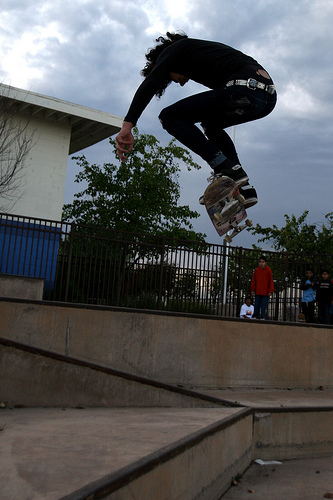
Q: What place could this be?
A: It is a park.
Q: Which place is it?
A: It is a park.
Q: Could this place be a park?
A: Yes, it is a park.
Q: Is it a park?
A: Yes, it is a park.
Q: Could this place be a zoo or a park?
A: It is a park.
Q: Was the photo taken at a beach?
A: No, the picture was taken in a park.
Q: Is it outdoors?
A: Yes, it is outdoors.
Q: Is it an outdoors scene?
A: Yes, it is outdoors.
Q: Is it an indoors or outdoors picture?
A: It is outdoors.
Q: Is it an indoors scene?
A: No, it is outdoors.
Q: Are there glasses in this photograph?
A: No, there are no glasses.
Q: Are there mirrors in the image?
A: No, there are no mirrors.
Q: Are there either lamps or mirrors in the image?
A: No, there are no mirrors or lamps.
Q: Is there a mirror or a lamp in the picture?
A: No, there are no mirrors or lamps.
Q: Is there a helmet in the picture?
A: No, there are no helmets.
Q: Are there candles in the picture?
A: No, there are no candles.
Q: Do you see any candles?
A: No, there are no candles.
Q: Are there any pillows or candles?
A: No, there are no candles or pillows.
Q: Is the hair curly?
A: Yes, the hair is curly.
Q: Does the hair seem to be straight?
A: No, the hair is curly.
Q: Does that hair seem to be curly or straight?
A: The hair is curly.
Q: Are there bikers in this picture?
A: No, there are no bikers.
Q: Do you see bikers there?
A: No, there are no bikers.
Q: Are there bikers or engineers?
A: No, there are no bikers or engineers.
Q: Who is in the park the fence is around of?
A: The boy is in the park.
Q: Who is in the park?
A: The boy is in the park.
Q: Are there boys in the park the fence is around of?
A: Yes, there is a boy in the park.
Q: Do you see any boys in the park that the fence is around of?
A: Yes, there is a boy in the park.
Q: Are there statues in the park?
A: No, there is a boy in the park.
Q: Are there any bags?
A: No, there are no bags.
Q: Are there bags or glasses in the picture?
A: No, there are no bags or glasses.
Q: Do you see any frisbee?
A: No, there are no frisbees.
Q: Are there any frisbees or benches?
A: No, there are no frisbees or benches.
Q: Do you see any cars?
A: No, there are no cars.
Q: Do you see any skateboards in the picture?
A: Yes, there is a skateboard.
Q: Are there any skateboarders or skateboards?
A: Yes, there is a skateboard.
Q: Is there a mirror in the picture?
A: No, there are no mirrors.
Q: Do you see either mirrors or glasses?
A: No, there are no mirrors or glasses.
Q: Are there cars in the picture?
A: No, there are no cars.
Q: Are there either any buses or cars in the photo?
A: No, there are no cars or buses.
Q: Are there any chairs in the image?
A: No, there are no chairs.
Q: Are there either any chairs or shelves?
A: No, there are no chairs or shelves.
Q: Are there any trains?
A: No, there are no trains.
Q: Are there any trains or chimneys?
A: No, there are no trains or chimneys.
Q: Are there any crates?
A: No, there are no crates.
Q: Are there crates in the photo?
A: No, there are no crates.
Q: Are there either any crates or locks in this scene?
A: No, there are no crates or locks.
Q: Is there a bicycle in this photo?
A: No, there are no bicycles.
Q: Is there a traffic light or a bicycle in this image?
A: No, there are no bicycles or traffic lights.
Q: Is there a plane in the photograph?
A: No, there are no airplanes.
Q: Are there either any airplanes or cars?
A: No, there are no airplanes or cars.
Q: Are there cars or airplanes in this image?
A: No, there are no airplanes or cars.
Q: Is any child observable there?
A: Yes, there is a child.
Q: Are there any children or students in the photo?
A: Yes, there is a child.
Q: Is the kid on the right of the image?
A: Yes, the kid is on the right of the image.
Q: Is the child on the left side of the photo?
A: No, the child is on the right of the image.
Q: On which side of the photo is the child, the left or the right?
A: The child is on the right of the image.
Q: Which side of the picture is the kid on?
A: The kid is on the right of the image.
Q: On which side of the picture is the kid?
A: The kid is on the right of the image.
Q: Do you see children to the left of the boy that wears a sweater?
A: Yes, there is a child to the left of the boy.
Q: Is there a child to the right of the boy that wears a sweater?
A: No, the child is to the left of the boy.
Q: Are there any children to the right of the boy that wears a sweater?
A: No, the child is to the left of the boy.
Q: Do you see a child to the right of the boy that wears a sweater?
A: No, the child is to the left of the boy.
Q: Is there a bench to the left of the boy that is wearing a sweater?
A: No, there is a child to the left of the boy.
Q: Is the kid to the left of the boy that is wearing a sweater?
A: Yes, the kid is to the left of the boy.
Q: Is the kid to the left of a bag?
A: No, the kid is to the left of the boy.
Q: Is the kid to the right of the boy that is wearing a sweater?
A: No, the kid is to the left of the boy.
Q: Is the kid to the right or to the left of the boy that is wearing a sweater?
A: The kid is to the left of the boy.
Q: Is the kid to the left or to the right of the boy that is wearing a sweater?
A: The kid is to the left of the boy.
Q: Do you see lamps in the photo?
A: No, there are no lamps.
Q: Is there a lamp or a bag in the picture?
A: No, there are no lamps or bags.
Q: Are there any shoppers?
A: No, there are no shoppers.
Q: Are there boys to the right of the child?
A: Yes, there are boys to the right of the child.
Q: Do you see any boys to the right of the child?
A: Yes, there are boys to the right of the child.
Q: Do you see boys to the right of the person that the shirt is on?
A: Yes, there are boys to the right of the child.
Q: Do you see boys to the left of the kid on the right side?
A: No, the boys are to the right of the child.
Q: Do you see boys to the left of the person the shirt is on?
A: No, the boys are to the right of the child.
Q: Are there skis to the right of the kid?
A: No, there are boys to the right of the kid.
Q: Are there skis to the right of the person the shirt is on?
A: No, there are boys to the right of the kid.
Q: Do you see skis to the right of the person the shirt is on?
A: No, there are boys to the right of the kid.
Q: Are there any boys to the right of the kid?
A: Yes, there are boys to the right of the kid.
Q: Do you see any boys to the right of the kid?
A: Yes, there are boys to the right of the kid.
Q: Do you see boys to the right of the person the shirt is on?
A: Yes, there are boys to the right of the kid.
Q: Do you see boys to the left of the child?
A: No, the boys are to the right of the child.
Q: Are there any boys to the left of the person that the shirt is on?
A: No, the boys are to the right of the child.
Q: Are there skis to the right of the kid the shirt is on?
A: No, there are boys to the right of the kid.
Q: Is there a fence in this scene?
A: Yes, there is a fence.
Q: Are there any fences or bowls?
A: Yes, there is a fence.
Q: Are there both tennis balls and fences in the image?
A: No, there is a fence but no tennis balls.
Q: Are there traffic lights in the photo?
A: No, there are no traffic lights.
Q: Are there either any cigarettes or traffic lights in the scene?
A: No, there are no traffic lights or cigarettes.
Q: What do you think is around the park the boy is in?
A: The fence is around the park.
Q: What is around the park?
A: The fence is around the park.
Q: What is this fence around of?
A: The fence is around the park.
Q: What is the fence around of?
A: The fence is around the park.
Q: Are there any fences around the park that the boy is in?
A: Yes, there is a fence around the park.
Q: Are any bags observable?
A: No, there are no bags.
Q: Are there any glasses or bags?
A: No, there are no bags or glasses.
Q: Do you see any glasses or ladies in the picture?
A: No, there are no glasses or ladies.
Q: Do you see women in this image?
A: No, there are no women.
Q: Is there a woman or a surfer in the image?
A: No, there are no women or surfers.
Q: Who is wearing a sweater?
A: The boy is wearing a sweater.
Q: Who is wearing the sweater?
A: The boy is wearing a sweater.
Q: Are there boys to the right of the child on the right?
A: Yes, there is a boy to the right of the child.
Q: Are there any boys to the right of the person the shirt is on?
A: Yes, there is a boy to the right of the child.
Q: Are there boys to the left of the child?
A: No, the boy is to the right of the child.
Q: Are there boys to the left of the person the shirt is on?
A: No, the boy is to the right of the child.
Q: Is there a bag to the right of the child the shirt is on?
A: No, there is a boy to the right of the kid.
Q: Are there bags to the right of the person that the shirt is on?
A: No, there is a boy to the right of the kid.